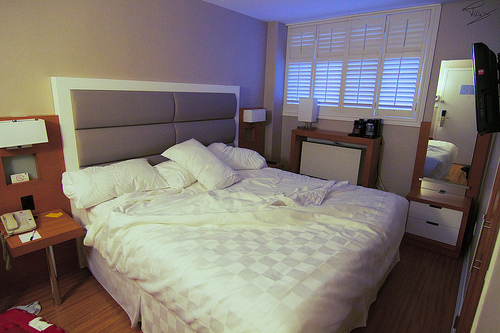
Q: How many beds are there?
A: One.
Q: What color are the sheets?
A: White.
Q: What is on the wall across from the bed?
A: A tv.